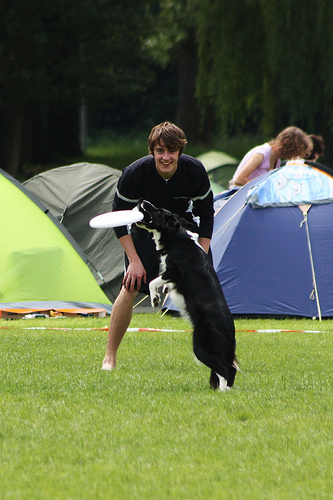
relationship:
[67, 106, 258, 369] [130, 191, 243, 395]
guy playing with dog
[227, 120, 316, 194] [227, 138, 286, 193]
woman wearing shirt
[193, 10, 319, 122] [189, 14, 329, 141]
leaves on tree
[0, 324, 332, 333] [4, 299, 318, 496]
rope on ground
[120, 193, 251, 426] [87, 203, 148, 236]
black dog catching frisbee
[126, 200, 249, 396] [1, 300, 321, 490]
dog jumping on field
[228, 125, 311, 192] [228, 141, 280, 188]
woman wearing shirt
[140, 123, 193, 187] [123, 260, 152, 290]
man has hand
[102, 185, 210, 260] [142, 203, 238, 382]
dog has hair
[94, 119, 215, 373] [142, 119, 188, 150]
boy has hair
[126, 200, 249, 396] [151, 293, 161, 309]
dog has paw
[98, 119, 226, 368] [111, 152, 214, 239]
boy wearing shirt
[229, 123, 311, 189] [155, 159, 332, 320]
boy behind tent